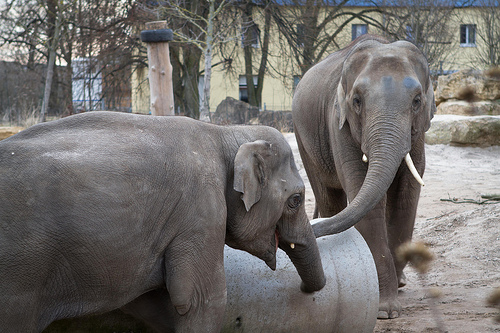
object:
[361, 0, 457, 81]
tree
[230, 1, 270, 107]
tree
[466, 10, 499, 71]
tree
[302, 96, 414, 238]
trunk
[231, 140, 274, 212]
ear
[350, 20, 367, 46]
window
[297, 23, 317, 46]
window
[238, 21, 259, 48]
window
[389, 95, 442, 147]
ground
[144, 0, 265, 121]
tree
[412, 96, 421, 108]
eye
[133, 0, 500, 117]
building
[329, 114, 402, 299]
leg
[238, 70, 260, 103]
window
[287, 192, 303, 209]
eye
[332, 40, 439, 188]
head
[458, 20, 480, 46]
window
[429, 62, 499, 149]
stones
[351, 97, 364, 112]
eye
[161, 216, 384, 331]
tube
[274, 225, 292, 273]
mouth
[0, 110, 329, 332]
elephant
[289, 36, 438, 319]
elephant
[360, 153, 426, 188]
tusk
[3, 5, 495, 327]
pen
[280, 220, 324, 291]
trunk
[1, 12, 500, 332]
enclosure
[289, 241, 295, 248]
tusk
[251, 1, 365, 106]
tree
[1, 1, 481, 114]
background